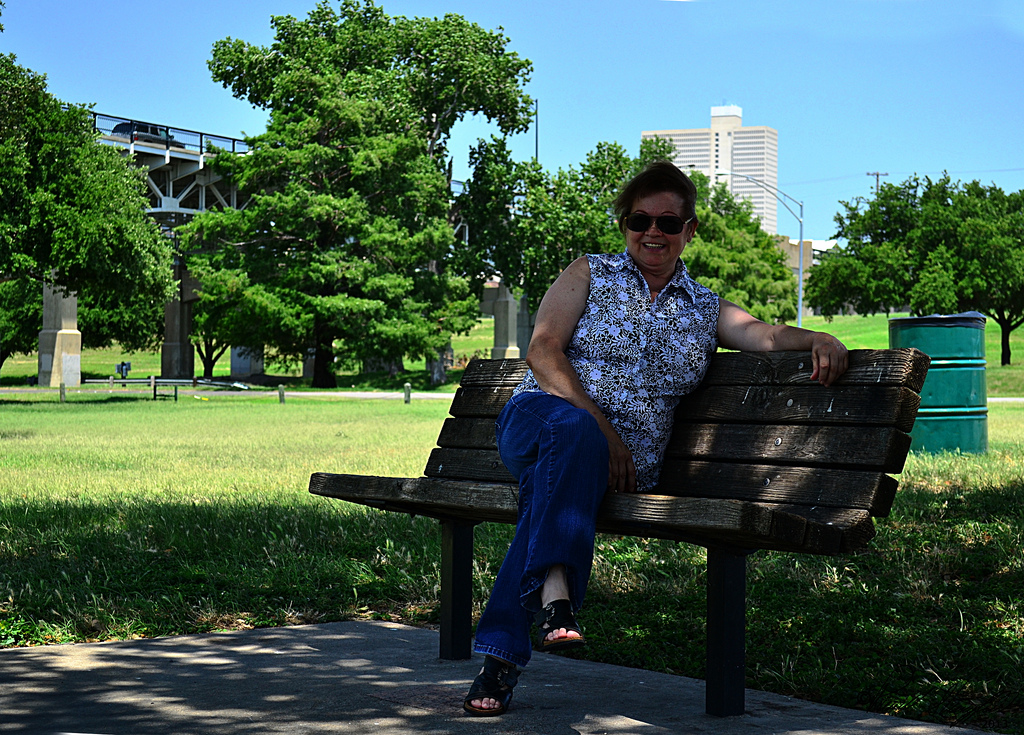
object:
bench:
[306, 346, 928, 717]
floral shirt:
[514, 247, 722, 490]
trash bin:
[889, 311, 990, 456]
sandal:
[539, 598, 586, 649]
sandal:
[463, 654, 520, 715]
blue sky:
[0, 0, 1024, 237]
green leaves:
[49, 251, 57, 261]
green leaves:
[492, 133, 498, 143]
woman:
[466, 162, 847, 716]